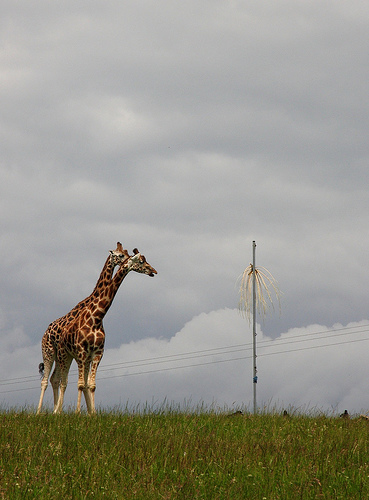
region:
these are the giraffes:
[31, 235, 157, 408]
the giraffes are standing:
[27, 235, 157, 412]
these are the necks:
[73, 263, 127, 315]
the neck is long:
[76, 263, 123, 312]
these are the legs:
[32, 357, 104, 414]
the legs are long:
[42, 352, 105, 417]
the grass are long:
[155, 413, 260, 498]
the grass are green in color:
[147, 403, 244, 498]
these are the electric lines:
[293, 327, 321, 350]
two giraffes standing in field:
[18, 225, 172, 411]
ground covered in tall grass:
[13, 415, 367, 493]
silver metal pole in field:
[237, 230, 273, 420]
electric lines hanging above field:
[127, 343, 244, 377]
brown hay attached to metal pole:
[232, 259, 284, 320]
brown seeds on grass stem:
[45, 438, 70, 455]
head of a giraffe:
[96, 241, 131, 261]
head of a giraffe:
[124, 238, 159, 273]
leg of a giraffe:
[66, 361, 90, 405]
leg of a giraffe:
[86, 366, 113, 418]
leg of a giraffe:
[19, 364, 54, 416]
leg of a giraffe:
[51, 377, 75, 416]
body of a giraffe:
[53, 313, 126, 369]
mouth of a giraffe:
[149, 267, 164, 276]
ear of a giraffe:
[107, 250, 121, 264]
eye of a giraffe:
[114, 252, 127, 262]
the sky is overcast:
[65, 90, 263, 188]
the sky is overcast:
[54, 110, 207, 159]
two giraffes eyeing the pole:
[31, 214, 269, 440]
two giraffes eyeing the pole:
[12, 208, 298, 435]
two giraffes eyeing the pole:
[30, 190, 277, 454]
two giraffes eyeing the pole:
[23, 202, 284, 449]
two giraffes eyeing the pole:
[27, 206, 281, 449]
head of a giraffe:
[122, 245, 161, 279]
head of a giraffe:
[107, 237, 135, 269]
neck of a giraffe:
[87, 270, 152, 317]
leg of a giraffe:
[85, 337, 115, 411]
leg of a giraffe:
[68, 358, 84, 416]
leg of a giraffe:
[57, 364, 75, 417]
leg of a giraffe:
[50, 362, 61, 399]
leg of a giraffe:
[38, 361, 56, 401]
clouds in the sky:
[166, 338, 256, 395]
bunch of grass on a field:
[132, 414, 343, 483]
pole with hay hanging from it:
[224, 221, 284, 427]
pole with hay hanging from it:
[226, 227, 282, 417]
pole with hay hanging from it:
[223, 230, 284, 425]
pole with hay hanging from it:
[218, 225, 287, 424]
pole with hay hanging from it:
[213, 223, 296, 419]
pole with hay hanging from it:
[224, 227, 294, 416]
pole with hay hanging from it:
[220, 227, 288, 418]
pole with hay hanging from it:
[215, 227, 286, 414]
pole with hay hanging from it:
[211, 224, 295, 425]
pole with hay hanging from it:
[224, 229, 295, 425]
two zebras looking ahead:
[26, 227, 168, 423]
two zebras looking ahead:
[24, 236, 167, 416]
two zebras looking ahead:
[24, 231, 165, 421]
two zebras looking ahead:
[28, 238, 164, 421]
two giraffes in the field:
[32, 228, 150, 401]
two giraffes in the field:
[34, 239, 168, 418]